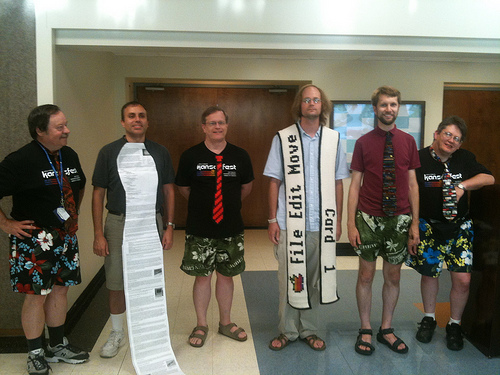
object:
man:
[177, 105, 255, 348]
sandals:
[186, 324, 210, 349]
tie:
[213, 152, 226, 222]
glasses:
[302, 95, 321, 104]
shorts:
[404, 215, 477, 277]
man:
[93, 99, 176, 359]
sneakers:
[100, 325, 128, 359]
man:
[263, 82, 351, 352]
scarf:
[275, 121, 341, 310]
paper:
[116, 143, 184, 374]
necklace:
[39, 147, 68, 211]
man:
[0, 103, 90, 374]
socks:
[109, 312, 126, 333]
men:
[405, 114, 496, 350]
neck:
[300, 116, 319, 135]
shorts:
[7, 228, 82, 296]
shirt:
[350, 126, 422, 218]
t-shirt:
[176, 140, 256, 240]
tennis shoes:
[24, 347, 53, 375]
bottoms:
[180, 233, 247, 279]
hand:
[3, 218, 37, 239]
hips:
[9, 220, 77, 251]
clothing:
[352, 126, 421, 264]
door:
[143, 92, 298, 228]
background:
[54, 41, 494, 140]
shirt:
[413, 144, 498, 222]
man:
[346, 86, 421, 356]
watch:
[267, 215, 279, 224]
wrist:
[265, 215, 281, 225]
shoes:
[444, 322, 465, 352]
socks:
[24, 334, 46, 350]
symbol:
[197, 163, 237, 172]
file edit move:
[287, 133, 304, 268]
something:
[263, 85, 348, 352]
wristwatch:
[161, 218, 175, 227]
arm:
[155, 145, 179, 229]